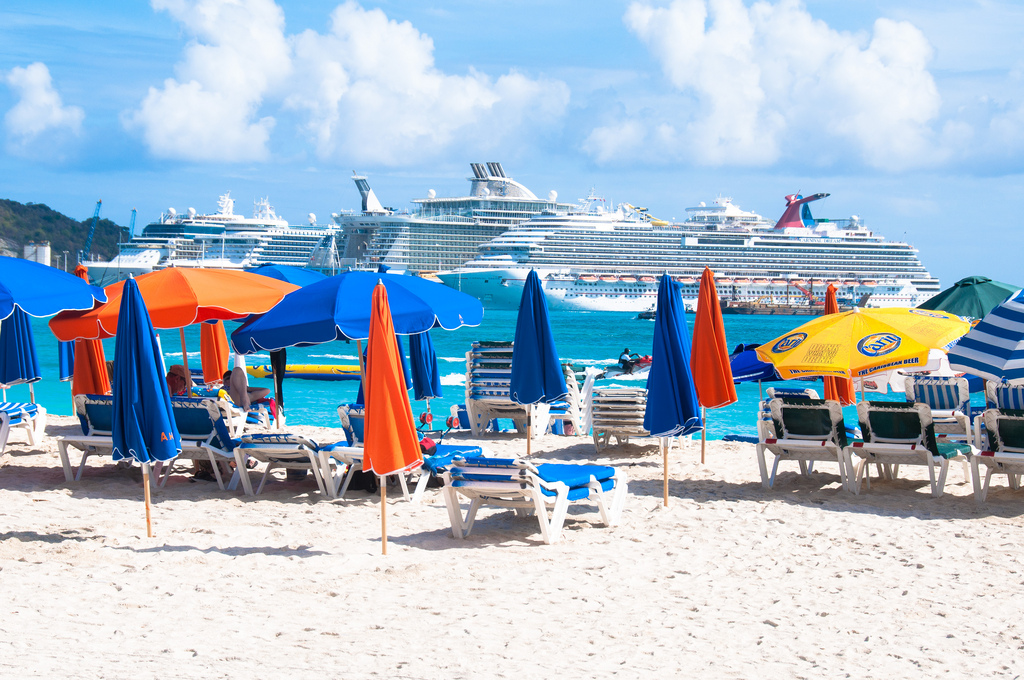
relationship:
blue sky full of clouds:
[10, 8, 1010, 193] [598, 13, 973, 173]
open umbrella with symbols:
[745, 296, 986, 389] [767, 327, 906, 364]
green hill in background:
[5, 192, 129, 259] [0, 197, 124, 267]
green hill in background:
[0, 191, 141, 269] [0, 197, 124, 267]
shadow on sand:
[635, 466, 1016, 514] [10, 510, 1019, 670]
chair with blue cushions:
[427, 449, 631, 554] [468, 428, 634, 523]